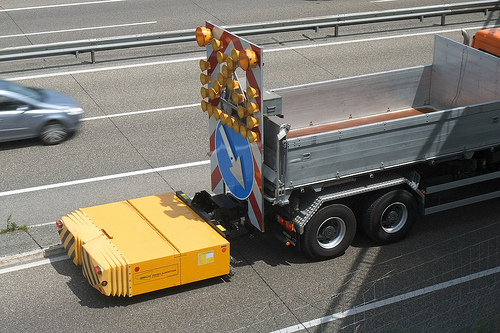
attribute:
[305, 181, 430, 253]
tire — black, truck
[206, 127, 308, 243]
lights — red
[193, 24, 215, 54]
light — yellow, electronic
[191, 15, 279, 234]
sign — blue, circle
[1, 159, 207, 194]
line — solid, white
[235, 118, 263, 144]
light — yellow, electronic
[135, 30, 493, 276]
truck — empty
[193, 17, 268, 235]
sign — red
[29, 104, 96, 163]
tire — black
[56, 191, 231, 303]
electronic sign — large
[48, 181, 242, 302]
train — yellow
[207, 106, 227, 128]
light — electronic, yellow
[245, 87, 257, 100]
light — yellow, electronic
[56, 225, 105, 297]
stripes — black, yellow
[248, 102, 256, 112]
light — electronic, yellow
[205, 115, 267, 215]
circle — blue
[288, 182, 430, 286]
tire — black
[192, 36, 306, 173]
sign — electronic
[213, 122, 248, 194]
arrow — white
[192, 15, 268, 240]
signals — yellow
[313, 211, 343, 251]
rim — silver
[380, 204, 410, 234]
rim — silver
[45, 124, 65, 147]
rim — silver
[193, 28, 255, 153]
light — yellow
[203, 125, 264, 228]
stripes — white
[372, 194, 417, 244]
rim — silver